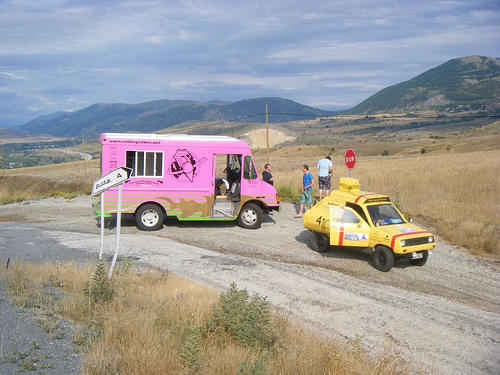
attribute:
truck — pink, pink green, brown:
[99, 136, 284, 226]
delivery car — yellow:
[305, 184, 437, 270]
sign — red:
[345, 149, 356, 167]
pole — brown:
[260, 99, 273, 167]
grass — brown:
[355, 158, 496, 221]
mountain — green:
[348, 57, 499, 116]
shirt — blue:
[300, 175, 316, 187]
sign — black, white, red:
[83, 169, 142, 194]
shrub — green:
[203, 295, 279, 346]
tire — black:
[138, 203, 162, 222]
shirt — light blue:
[318, 159, 328, 169]